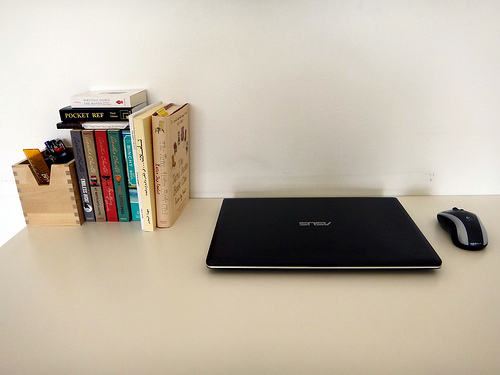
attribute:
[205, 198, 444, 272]
laptop — closed, black, an asus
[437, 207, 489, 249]
mouse — black, silver, gray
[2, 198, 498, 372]
table — tan, light tan, beige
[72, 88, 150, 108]
book — white, small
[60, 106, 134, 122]
book — black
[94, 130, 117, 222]
book — red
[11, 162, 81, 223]
desk container — wooden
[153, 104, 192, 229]
book — brown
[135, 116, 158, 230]
book — yellow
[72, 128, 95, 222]
book — purple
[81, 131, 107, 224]
book — brown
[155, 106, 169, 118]
bookmark — yellow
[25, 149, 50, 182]
ruler — orange